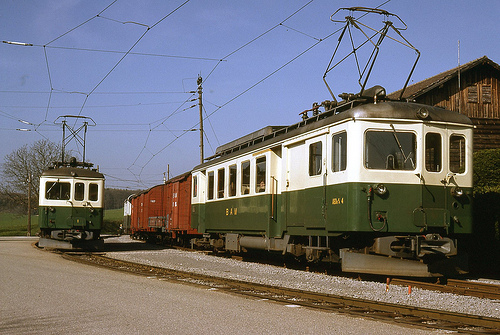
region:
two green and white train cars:
[35, 133, 498, 258]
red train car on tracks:
[120, 180, 198, 244]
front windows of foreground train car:
[356, 125, 470, 195]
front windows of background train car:
[42, 183, 94, 208]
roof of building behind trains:
[379, 45, 487, 112]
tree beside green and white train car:
[10, 140, 84, 223]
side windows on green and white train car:
[192, 128, 361, 209]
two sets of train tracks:
[35, 208, 479, 334]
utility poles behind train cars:
[54, 27, 448, 166]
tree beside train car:
[10, 147, 78, 238]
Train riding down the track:
[24, 134, 139, 271]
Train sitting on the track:
[132, 68, 449, 273]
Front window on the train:
[354, 119, 421, 169]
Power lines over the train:
[32, 41, 283, 144]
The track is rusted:
[120, 254, 292, 324]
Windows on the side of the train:
[192, 156, 282, 200]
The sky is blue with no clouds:
[192, 71, 323, 134]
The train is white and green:
[40, 163, 143, 255]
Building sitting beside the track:
[425, 48, 497, 123]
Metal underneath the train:
[221, 237, 408, 300]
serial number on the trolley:
[328, 196, 346, 208]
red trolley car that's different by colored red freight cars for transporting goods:
[126, 171, 198, 243]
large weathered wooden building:
[385, 54, 498, 152]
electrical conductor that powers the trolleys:
[52, 112, 95, 162]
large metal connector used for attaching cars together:
[380, 234, 465, 260]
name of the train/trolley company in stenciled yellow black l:
[222, 204, 237, 217]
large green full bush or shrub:
[470, 146, 498, 238]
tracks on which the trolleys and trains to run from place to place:
[26, 237, 498, 333]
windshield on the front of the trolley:
[44, 180, 99, 204]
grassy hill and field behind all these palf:
[0, 207, 125, 237]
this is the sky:
[182, 17, 207, 37]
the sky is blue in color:
[6, 4, 66, 35]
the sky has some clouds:
[103, 136, 140, 171]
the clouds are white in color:
[99, 136, 125, 155]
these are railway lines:
[143, 255, 462, 326]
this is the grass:
[3, 215, 20, 224]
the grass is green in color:
[2, 218, 23, 228]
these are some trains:
[21, 88, 498, 265]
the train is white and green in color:
[293, 173, 308, 215]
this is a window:
[254, 158, 267, 187]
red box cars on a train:
[127, 178, 192, 238]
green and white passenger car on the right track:
[190, 96, 472, 241]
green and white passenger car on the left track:
[34, 123, 107, 250]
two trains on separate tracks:
[40, 95, 466, 280]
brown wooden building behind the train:
[384, 50, 499, 169]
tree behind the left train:
[7, 140, 71, 233]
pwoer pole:
[196, 74, 205, 165]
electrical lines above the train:
[13, 9, 404, 128]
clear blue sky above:
[1, 2, 496, 187]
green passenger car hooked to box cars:
[128, 98, 470, 281]